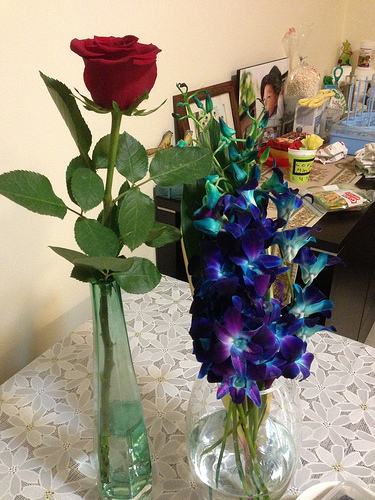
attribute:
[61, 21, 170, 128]
rose — red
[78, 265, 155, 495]
vase — clear, green, long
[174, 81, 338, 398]
flowers — purple, blue, colorful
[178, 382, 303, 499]
vase — transparent, wide, water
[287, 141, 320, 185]
container — neon green, green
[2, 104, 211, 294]
leaves — green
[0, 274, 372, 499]
table cloth — white, floral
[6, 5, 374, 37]
wall — white, clean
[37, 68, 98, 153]
leaf — green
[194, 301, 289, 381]
flower — purple, blue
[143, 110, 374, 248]
counter — clutters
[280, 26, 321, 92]
bag — plastic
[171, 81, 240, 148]
picture — brown